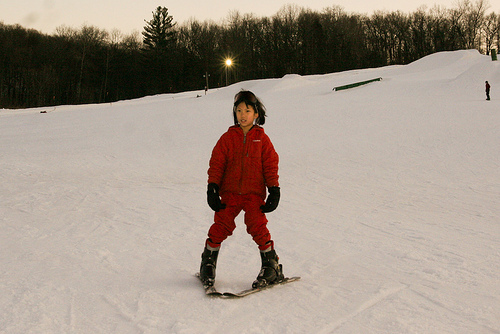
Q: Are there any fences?
A: No, there are no fences.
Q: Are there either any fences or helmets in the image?
A: No, there are no fences or helmets.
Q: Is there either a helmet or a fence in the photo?
A: No, there are no helmets or fences.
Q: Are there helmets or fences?
A: No, there are no helmets or fences.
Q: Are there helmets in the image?
A: No, there are no helmets.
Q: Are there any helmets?
A: No, there are no helmets.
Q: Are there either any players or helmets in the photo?
A: No, there are no helmets or players.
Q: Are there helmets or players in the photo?
A: No, there are no helmets or players.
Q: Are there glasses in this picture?
A: No, there are no glasses.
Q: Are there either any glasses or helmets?
A: No, there are no glasses or helmets.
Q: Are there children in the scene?
A: Yes, there is a child.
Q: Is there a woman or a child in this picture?
A: Yes, there is a child.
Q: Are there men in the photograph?
A: No, there are no men.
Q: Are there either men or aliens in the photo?
A: No, there are no men or aliens.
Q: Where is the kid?
A: The kid is in the snow.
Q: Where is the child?
A: The kid is in the snow.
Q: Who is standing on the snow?
A: The child is standing on the snow.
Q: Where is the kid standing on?
A: The kid is standing on the snow.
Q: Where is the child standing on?
A: The kid is standing on the snow.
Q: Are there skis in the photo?
A: Yes, there are skis.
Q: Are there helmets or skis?
A: Yes, there are skis.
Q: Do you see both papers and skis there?
A: No, there are skis but no papers.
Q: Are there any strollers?
A: No, there are no strollers.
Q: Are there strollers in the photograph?
A: No, there are no strollers.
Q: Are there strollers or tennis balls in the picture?
A: No, there are no strollers or tennis balls.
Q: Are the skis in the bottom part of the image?
A: Yes, the skis are in the bottom of the image.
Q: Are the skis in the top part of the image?
A: No, the skis are in the bottom of the image.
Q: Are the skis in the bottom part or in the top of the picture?
A: The skis are in the bottom of the image.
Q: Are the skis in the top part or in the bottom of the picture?
A: The skis are in the bottom of the image.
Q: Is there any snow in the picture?
A: Yes, there is snow.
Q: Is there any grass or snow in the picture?
A: Yes, there is snow.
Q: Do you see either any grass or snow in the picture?
A: Yes, there is snow.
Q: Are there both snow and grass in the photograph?
A: No, there is snow but no grass.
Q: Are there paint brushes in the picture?
A: No, there are no paint brushes.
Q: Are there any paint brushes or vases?
A: No, there are no paint brushes or vases.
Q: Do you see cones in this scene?
A: No, there are no cones.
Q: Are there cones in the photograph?
A: No, there are no cones.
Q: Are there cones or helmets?
A: No, there are no cones or helmets.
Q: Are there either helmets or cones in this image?
A: No, there are no cones or helmets.